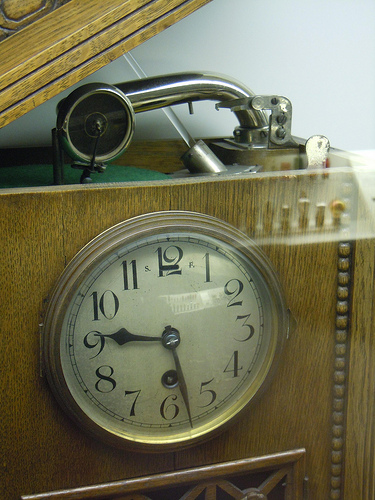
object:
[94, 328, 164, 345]
arm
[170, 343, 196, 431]
arm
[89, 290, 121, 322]
number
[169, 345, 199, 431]
hand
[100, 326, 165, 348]
hand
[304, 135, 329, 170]
ground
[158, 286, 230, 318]
reflection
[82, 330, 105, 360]
9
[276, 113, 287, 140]
screws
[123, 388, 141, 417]
number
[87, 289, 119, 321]
writing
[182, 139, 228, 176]
cylinder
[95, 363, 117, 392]
number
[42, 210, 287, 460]
clock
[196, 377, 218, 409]
number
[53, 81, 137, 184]
gauge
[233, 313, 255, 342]
number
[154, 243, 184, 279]
number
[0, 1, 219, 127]
wooden lid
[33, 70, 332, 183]
metal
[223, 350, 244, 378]
numbers